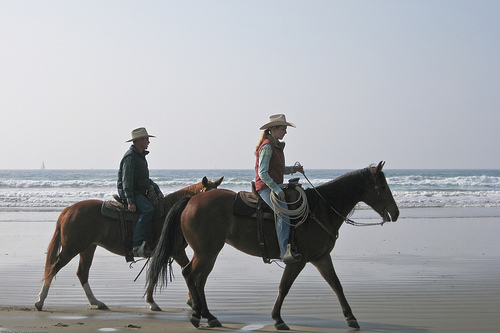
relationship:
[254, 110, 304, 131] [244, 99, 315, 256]
hat on woman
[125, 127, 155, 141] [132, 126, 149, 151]
hat on mans head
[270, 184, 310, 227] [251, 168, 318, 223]
lasso on lap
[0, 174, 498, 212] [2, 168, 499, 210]
foam in water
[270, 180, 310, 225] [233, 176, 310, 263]
lasso attached to saddle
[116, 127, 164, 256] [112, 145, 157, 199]
man wearing a green vest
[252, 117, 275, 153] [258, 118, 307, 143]
blonde ponytail on womans head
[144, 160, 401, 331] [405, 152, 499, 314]
horses ridden on beach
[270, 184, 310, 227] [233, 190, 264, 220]
lasso on a saddle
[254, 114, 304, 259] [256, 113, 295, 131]
woman wearing a hat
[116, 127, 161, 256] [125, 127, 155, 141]
man wearing a cowboy hat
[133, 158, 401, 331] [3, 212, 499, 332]
horses walking on a beach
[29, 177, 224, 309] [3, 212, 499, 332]
horses walking on a beach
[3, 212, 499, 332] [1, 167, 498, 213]
beach by ocean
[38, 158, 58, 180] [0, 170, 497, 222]
boat in ocean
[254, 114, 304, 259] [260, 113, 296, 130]
woman wearing hat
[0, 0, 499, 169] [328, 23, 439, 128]
clouds in sky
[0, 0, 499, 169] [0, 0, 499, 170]
clouds in sky